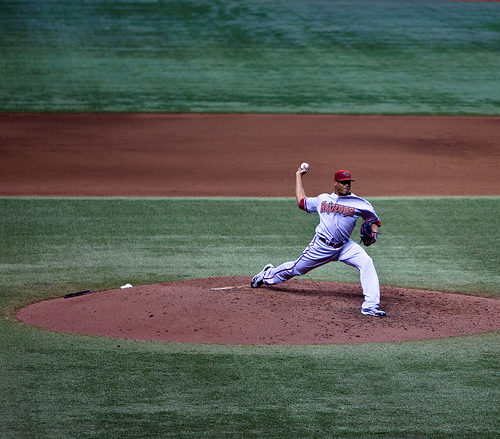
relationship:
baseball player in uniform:
[254, 163, 385, 319] [264, 193, 380, 307]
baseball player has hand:
[254, 163, 385, 319] [296, 165, 307, 171]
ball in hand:
[300, 162, 310, 168] [296, 165, 307, 171]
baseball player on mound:
[254, 163, 385, 319] [17, 275, 499, 343]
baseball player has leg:
[254, 163, 385, 319] [265, 239, 335, 285]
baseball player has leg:
[254, 163, 385, 319] [341, 233, 384, 306]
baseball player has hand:
[254, 163, 385, 319] [359, 221, 379, 244]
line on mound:
[210, 280, 251, 291] [17, 275, 499, 343]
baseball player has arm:
[254, 163, 385, 319] [292, 168, 317, 211]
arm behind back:
[292, 168, 317, 211] [311, 188, 368, 205]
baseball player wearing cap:
[254, 163, 385, 319] [335, 171, 355, 184]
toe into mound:
[250, 277, 261, 290] [17, 275, 499, 343]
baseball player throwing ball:
[254, 163, 385, 319] [300, 162, 310, 168]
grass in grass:
[2, 2, 499, 436] [2, 2, 499, 436]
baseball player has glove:
[254, 163, 385, 319] [360, 223, 375, 244]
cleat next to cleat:
[252, 264, 274, 291] [362, 306, 383, 318]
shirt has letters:
[306, 192, 379, 241] [320, 199, 355, 218]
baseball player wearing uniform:
[254, 163, 385, 319] [264, 193, 380, 307]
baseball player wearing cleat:
[254, 163, 385, 319] [252, 264, 274, 291]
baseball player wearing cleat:
[254, 163, 385, 319] [362, 306, 383, 318]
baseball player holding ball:
[254, 163, 385, 319] [300, 162, 310, 168]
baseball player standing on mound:
[254, 163, 385, 319] [17, 275, 499, 343]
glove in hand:
[360, 223, 375, 244] [359, 221, 379, 244]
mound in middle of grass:
[17, 275, 499, 343] [2, 2, 499, 436]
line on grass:
[1, 190, 499, 202] [2, 2, 499, 436]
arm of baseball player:
[292, 168, 317, 211] [254, 163, 385, 319]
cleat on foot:
[362, 306, 383, 318] [358, 303, 385, 320]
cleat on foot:
[252, 264, 274, 291] [250, 263, 276, 286]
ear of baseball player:
[333, 180, 339, 188] [254, 163, 385, 319]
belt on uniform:
[316, 235, 351, 250] [264, 193, 380, 307]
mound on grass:
[17, 275, 499, 343] [2, 2, 499, 436]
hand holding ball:
[296, 165, 307, 171] [300, 162, 310, 168]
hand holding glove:
[359, 221, 379, 244] [360, 223, 375, 244]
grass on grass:
[2, 2, 499, 436] [2, 2, 499, 436]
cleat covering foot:
[252, 264, 274, 291] [250, 263, 276, 286]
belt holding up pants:
[316, 235, 351, 250] [262, 236, 382, 304]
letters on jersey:
[320, 199, 355, 218] [306, 192, 379, 241]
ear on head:
[333, 180, 339, 188] [334, 176, 349, 193]